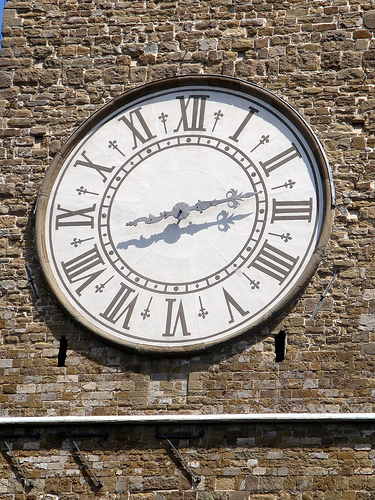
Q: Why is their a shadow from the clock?
A: Sun.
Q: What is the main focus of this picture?
A: Clock.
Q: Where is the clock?
A: Wall.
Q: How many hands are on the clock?
A: 2.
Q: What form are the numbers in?
A: Roman numeral.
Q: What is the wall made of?
A: Brick.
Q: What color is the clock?
A: White.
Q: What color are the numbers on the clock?
A: Black.